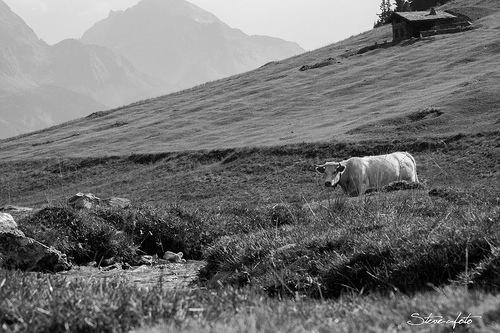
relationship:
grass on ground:
[0, 0, 500, 333] [44, 168, 333, 297]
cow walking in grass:
[292, 147, 434, 194] [8, 33, 484, 323]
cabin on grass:
[383, 7, 458, 42] [10, 19, 477, 306]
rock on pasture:
[0, 192, 187, 272] [6, 3, 497, 330]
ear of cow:
[316, 163, 329, 171] [304, 152, 448, 195]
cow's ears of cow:
[337, 165, 345, 172] [304, 152, 448, 195]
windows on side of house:
[390, 24, 412, 35] [385, 8, 465, 46]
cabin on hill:
[377, 0, 476, 55] [386, 31, 481, 121]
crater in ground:
[348, 97, 461, 137] [40, 15, 483, 308]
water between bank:
[56, 260, 212, 292] [6, 194, 498, 279]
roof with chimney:
[396, 3, 459, 24] [425, 5, 442, 16]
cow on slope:
[315, 152, 419, 197] [0, 16, 497, 163]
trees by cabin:
[374, 0, 442, 28] [390, 10, 472, 44]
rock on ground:
[0, 192, 187, 272] [7, 263, 489, 328]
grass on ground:
[0, 0, 500, 333] [7, 70, 499, 328]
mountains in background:
[3, 0, 320, 134] [3, 3, 418, 143]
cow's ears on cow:
[337, 165, 345, 172] [307, 148, 428, 202]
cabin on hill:
[383, 7, 458, 42] [143, 43, 453, 128]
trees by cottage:
[374, 2, 396, 24] [376, 3, 476, 59]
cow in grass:
[315, 152, 419, 197] [1, 0, 498, 332]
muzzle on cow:
[322, 180, 333, 189] [314, 147, 421, 197]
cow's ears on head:
[337, 165, 345, 172] [315, 155, 347, 189]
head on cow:
[315, 155, 347, 189] [314, 147, 421, 197]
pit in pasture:
[344, 77, 474, 163] [6, 3, 497, 330]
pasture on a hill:
[0, 0, 500, 333] [113, 62, 429, 270]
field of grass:
[10, 113, 492, 323] [1, 159, 496, 331]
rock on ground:
[0, 192, 187, 272] [7, 4, 492, 327]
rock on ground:
[137, 244, 189, 267] [7, 4, 492, 327]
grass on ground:
[241, 204, 376, 251] [7, 4, 492, 327]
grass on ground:
[0, 0, 500, 333] [7, 4, 492, 327]